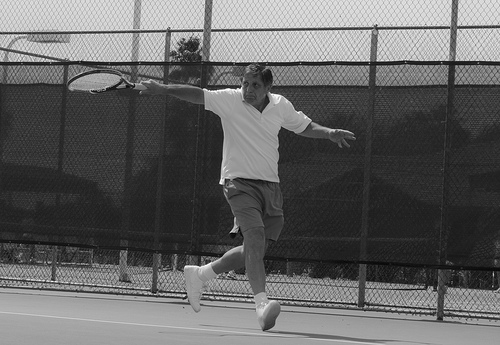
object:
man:
[141, 63, 354, 331]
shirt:
[205, 88, 312, 184]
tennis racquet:
[67, 70, 147, 95]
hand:
[139, 79, 164, 96]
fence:
[0, 0, 498, 321]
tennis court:
[0, 286, 499, 343]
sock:
[200, 263, 217, 281]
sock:
[254, 292, 266, 302]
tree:
[166, 37, 210, 258]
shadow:
[266, 329, 417, 344]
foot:
[185, 265, 204, 312]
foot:
[257, 301, 280, 331]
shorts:
[223, 178, 283, 241]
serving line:
[1, 313, 381, 344]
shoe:
[184, 265, 203, 312]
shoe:
[256, 301, 281, 330]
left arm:
[280, 96, 329, 139]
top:
[0, 23, 499, 35]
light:
[3, 33, 71, 84]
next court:
[0, 246, 499, 311]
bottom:
[0, 282, 500, 324]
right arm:
[167, 83, 219, 115]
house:
[287, 167, 428, 259]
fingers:
[342, 139, 350, 147]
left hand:
[329, 129, 356, 148]